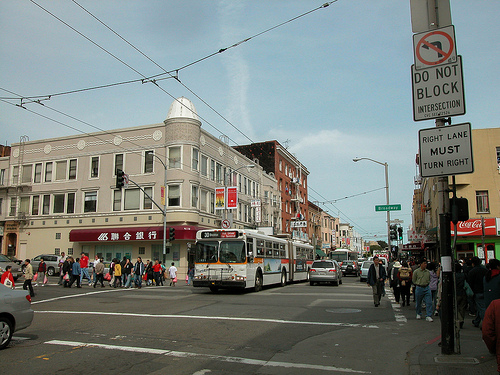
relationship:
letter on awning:
[96, 229, 110, 243] [68, 226, 213, 244]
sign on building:
[447, 215, 500, 242] [427, 120, 500, 320]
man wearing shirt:
[406, 256, 438, 324] [411, 265, 440, 289]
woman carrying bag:
[31, 255, 50, 290] [31, 269, 40, 287]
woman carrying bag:
[31, 255, 50, 290] [41, 272, 51, 288]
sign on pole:
[373, 202, 404, 214] [381, 159, 394, 291]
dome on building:
[159, 88, 205, 129] [1, 95, 285, 286]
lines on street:
[8, 279, 406, 374] [1, 229, 499, 374]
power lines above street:
[1, 1, 391, 236] [1, 229, 499, 374]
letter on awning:
[110, 230, 121, 243] [68, 226, 213, 244]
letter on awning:
[122, 229, 134, 242] [68, 226, 213, 244]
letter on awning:
[135, 229, 146, 242] [68, 226, 213, 244]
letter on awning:
[147, 227, 160, 242] [68, 226, 213, 244]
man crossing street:
[406, 256, 438, 324] [1, 229, 499, 374]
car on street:
[337, 257, 364, 279] [1, 229, 499, 374]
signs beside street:
[406, 0, 478, 360] [1, 229, 499, 374]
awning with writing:
[68, 226, 213, 244] [96, 229, 158, 241]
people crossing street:
[1, 249, 181, 300] [1, 229, 499, 374]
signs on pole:
[406, 0, 478, 360] [424, 2, 458, 354]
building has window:
[427, 120, 500, 320] [471, 183, 495, 217]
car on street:
[307, 254, 345, 289] [1, 229, 499, 374]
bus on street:
[192, 225, 320, 293] [1, 229, 499, 374]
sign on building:
[213, 183, 228, 212] [1, 95, 285, 286]